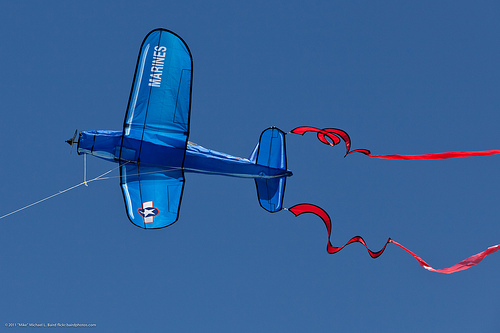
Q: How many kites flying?
A: One.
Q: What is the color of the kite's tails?
A: Red.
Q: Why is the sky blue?
A: It's clear day.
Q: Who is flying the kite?
A: A person.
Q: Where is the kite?
A: Flying.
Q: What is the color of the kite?
A: Blue.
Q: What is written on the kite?
A: Marines.